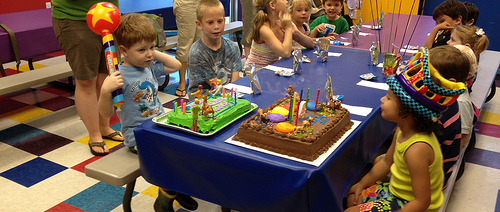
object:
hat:
[382, 44, 462, 124]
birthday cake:
[166, 82, 241, 134]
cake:
[227, 90, 354, 164]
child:
[362, 72, 461, 209]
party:
[73, 0, 335, 195]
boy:
[90, 15, 175, 145]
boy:
[185, 0, 252, 95]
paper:
[354, 75, 393, 91]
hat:
[376, 41, 477, 133]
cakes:
[243, 90, 360, 163]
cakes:
[155, 75, 349, 142]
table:
[133, 10, 493, 210]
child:
[92, 19, 222, 184]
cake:
[231, 73, 352, 160]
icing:
[231, 131, 353, 160]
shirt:
[391, 144, 448, 208]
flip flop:
[86, 136, 108, 157]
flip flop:
[101, 124, 126, 148]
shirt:
[47, 0, 117, 20]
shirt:
[442, 98, 467, 175]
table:
[113, 59, 435, 197]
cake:
[234, 73, 362, 163]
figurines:
[172, 85, 233, 115]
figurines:
[276, 82, 332, 125]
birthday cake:
[241, 85, 358, 160]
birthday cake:
[153, 86, 248, 130]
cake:
[245, 67, 343, 169]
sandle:
[86, 137, 107, 155]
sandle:
[98, 129, 124, 140]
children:
[86, 0, 488, 208]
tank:
[386, 129, 450, 210]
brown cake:
[233, 104, 354, 161]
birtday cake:
[225, 101, 361, 152]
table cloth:
[137, 35, 427, 210]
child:
[323, 42, 452, 209]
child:
[359, 57, 466, 202]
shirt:
[369, 125, 464, 210]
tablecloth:
[135, 123, 305, 201]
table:
[117, 20, 400, 196]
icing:
[169, 103, 251, 125]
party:
[6, 6, 494, 209]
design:
[86, 2, 116, 27]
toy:
[77, 0, 131, 110]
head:
[379, 72, 439, 136]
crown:
[386, 47, 468, 120]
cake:
[168, 93, 252, 133]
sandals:
[81, 128, 130, 157]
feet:
[81, 123, 130, 157]